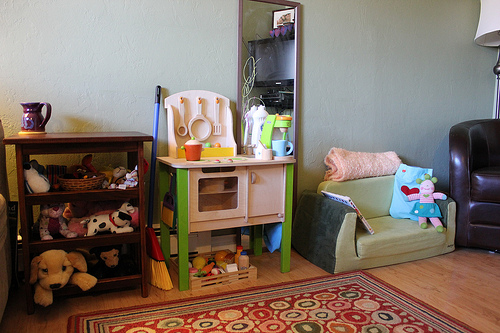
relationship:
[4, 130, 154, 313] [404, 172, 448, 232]
shelving unit full of doll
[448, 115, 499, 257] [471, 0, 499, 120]
couch in front of lamp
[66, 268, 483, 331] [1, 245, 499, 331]
rug on top of floor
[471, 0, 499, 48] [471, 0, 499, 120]
lamp shade on lamp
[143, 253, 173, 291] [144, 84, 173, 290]
thistles of broom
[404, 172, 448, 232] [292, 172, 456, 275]
doll on top of couch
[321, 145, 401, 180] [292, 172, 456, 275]
blanket on top of couch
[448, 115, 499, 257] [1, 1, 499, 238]
couch against wall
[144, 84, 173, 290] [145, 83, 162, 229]
broom has handle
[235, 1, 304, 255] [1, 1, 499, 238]
mirror hanging on wall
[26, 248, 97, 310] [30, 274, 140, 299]
dog on top of shelf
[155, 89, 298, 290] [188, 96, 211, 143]
kitchen playset with cooking pan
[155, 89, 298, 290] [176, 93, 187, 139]
kitchen playset with spoon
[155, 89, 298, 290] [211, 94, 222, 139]
kitchen playset with spatula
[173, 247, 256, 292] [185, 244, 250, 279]
crate of play food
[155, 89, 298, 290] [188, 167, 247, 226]
kitchen playset has oven door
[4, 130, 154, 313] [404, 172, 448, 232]
shelving unit with doll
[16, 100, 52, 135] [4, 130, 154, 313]
cup on top of shelving unit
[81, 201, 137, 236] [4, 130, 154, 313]
stuffed animal inside of shelving unit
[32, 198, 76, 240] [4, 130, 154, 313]
stuffed animal inside of shelving unit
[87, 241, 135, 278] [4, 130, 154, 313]
stuffed animal inside of shelving unit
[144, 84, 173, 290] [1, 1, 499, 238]
broom leaning against wall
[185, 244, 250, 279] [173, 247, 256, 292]
play food inside of crate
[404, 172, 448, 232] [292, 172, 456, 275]
doll sitting on couch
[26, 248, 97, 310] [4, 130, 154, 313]
dog sitting in shelving unit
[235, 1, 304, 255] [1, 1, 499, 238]
mirror hanging from wall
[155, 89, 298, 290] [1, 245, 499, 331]
kitchen playset on top of floor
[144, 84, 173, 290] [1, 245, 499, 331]
broom standing on floor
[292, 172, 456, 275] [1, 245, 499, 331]
couch on top of floor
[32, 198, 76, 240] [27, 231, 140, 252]
stuffed animal on top of shelf